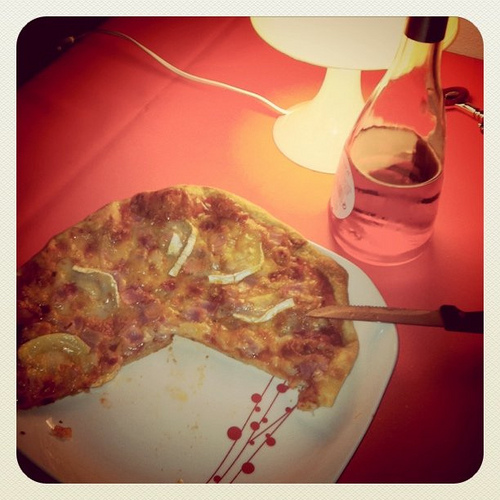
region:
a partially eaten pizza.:
[16, 186, 368, 426]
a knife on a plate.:
[300, 291, 485, 348]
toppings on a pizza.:
[229, 280, 304, 350]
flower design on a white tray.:
[181, 347, 312, 496]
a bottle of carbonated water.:
[325, 3, 469, 249]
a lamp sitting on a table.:
[232, 16, 459, 183]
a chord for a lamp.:
[85, 15, 293, 126]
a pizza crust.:
[311, 261, 361, 412]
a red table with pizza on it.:
[21, 21, 484, 471]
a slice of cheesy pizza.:
[160, 268, 352, 391]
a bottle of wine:
[303, 0, 468, 273]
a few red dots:
[221, 381, 298, 465]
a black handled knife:
[303, 302, 480, 346]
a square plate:
[16, 182, 424, 472]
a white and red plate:
[15, 186, 430, 474]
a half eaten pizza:
[8, 184, 383, 448]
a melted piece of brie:
[63, 237, 135, 320]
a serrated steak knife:
[293, 288, 468, 342]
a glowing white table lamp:
[222, 0, 436, 225]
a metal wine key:
[411, 70, 497, 142]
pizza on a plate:
[21, 172, 342, 422]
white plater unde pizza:
[127, 363, 238, 448]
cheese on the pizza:
[208, 256, 293, 359]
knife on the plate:
[321, 272, 423, 354]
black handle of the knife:
[433, 291, 478, 358]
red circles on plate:
[215, 393, 267, 470]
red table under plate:
[101, 93, 188, 152]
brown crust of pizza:
[316, 248, 343, 280]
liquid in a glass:
[354, 131, 450, 258]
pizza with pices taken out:
[98, 193, 302, 425]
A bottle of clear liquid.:
[327, 29, 449, 267]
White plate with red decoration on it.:
[0, 235, 400, 492]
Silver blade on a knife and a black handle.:
[303, 301, 486, 336]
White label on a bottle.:
[330, 149, 357, 221]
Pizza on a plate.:
[8, 181, 360, 410]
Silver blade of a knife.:
[304, 296, 442, 326]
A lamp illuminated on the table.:
[239, 11, 460, 174]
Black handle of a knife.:
[441, 302, 486, 337]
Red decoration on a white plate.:
[204, 359, 299, 487]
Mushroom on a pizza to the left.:
[19, 334, 90, 369]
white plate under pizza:
[137, 361, 228, 428]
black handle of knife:
[447, 297, 481, 350]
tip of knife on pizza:
[306, 295, 339, 340]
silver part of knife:
[306, 292, 436, 360]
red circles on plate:
[199, 386, 289, 493]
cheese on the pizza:
[95, 203, 275, 321]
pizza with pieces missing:
[60, 182, 320, 415]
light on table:
[243, 66, 362, 177]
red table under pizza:
[376, 382, 458, 484]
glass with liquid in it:
[353, 114, 442, 221]